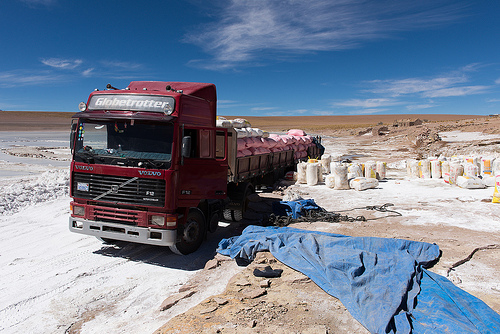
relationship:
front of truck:
[68, 112, 180, 246] [67, 120, 184, 239]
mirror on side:
[69, 117, 79, 153] [68, 117, 85, 203]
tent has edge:
[224, 218, 497, 334] [236, 237, 438, 254]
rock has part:
[248, 266, 282, 279] [255, 262, 275, 277]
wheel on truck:
[171, 203, 209, 255] [67, 120, 184, 239]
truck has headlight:
[67, 120, 184, 239] [147, 211, 168, 228]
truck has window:
[67, 120, 184, 239] [177, 127, 204, 159]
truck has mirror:
[67, 120, 184, 239] [69, 117, 79, 153]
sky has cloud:
[10, 8, 493, 73] [197, 11, 292, 63]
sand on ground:
[297, 157, 489, 193] [319, 188, 479, 204]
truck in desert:
[67, 120, 184, 239] [7, 112, 496, 333]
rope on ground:
[267, 204, 403, 225] [231, 276, 308, 327]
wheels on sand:
[171, 203, 209, 255] [0, 180, 64, 327]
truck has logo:
[67, 120, 184, 239] [93, 176, 140, 205]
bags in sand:
[297, 157, 489, 193] [0, 180, 64, 327]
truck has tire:
[67, 120, 184, 239] [171, 203, 209, 255]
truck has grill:
[67, 120, 184, 239] [72, 174, 166, 205]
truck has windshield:
[67, 120, 184, 239] [75, 117, 176, 167]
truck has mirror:
[67, 120, 184, 239] [181, 133, 192, 161]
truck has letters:
[67, 120, 184, 239] [89, 91, 174, 116]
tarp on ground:
[224, 218, 497, 334] [231, 276, 308, 327]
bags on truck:
[238, 130, 309, 158] [67, 120, 184, 239]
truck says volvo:
[67, 120, 184, 239] [74, 162, 165, 177]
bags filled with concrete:
[297, 157, 489, 193] [323, 152, 330, 159]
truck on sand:
[67, 120, 184, 239] [0, 180, 64, 327]